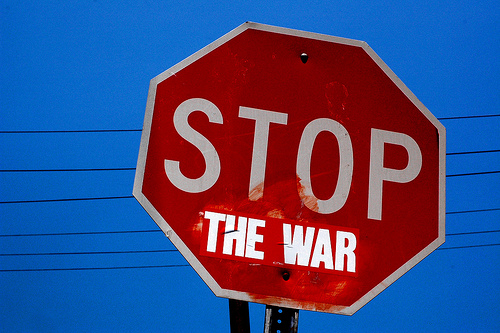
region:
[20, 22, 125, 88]
The sky is blue.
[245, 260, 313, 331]
A pole attached to a stop sign.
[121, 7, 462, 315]
A stop sign is red and white.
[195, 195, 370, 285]
A sticker that says the war has been added to the stop sign.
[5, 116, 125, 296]
Power lines are behind the stop sign.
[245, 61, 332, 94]
The background of the stop sign is red.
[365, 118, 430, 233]
The letter P on a stop sign.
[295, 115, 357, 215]
The letter O on a stop sign.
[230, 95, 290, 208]
The letter T on a stop sign.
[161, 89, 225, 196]
The letter S on a stop sign.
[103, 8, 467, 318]
red and white sign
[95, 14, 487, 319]
stop sign with sticker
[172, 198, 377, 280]
red and white sticker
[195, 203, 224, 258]
large white letter on sticker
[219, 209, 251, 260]
large white letter on sticker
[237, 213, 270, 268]
large white letter on sticker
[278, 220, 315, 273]
large white letter on sticker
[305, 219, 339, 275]
large white letter on sticker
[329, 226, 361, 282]
large white letter on sticker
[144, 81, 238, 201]
large white letter on sign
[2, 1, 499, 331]
The sky is blue.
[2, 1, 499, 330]
The sky is clear.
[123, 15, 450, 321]
The sign is red.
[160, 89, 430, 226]
White text on sign.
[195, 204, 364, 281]
Red sticker on sign.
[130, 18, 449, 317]
The sign is octagon.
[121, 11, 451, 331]
Sign on a pole.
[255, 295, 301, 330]
the pole is metal.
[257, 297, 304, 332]
The pole is black.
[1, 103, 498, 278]
the wires are black.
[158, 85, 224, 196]
the letter S on the stop sign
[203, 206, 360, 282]
a red and white sticker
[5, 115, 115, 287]
telephone lines in the sky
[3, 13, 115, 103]
crystal blue sky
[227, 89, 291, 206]
the letter T from the stop sign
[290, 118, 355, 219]
the letter O from the stop sign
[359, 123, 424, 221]
the letter P from the stop sign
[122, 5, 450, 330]
a red and white stop sign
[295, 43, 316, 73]
a bolt to hold the stop sign on the pole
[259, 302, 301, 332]
top of the stand for the stop sign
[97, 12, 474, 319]
vandalized red stop sign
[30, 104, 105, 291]
power lines strung through the air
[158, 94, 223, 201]
white ess on a red background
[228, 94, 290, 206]
white tee on a red background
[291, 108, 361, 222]
white oh on a red background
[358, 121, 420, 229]
white pee on a red background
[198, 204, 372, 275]
words added to a stop sign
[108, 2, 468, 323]
stop sign with graffitit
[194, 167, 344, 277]
scratched and smeared paint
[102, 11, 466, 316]
stop sign with shite trim